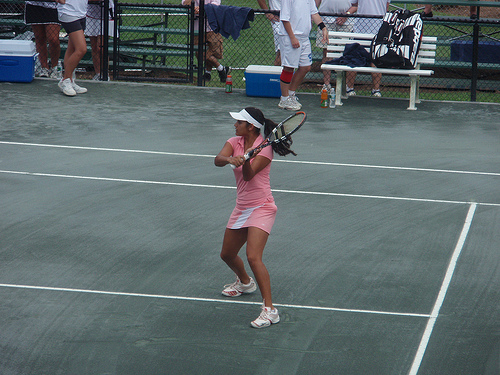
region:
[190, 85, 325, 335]
A woman playing tennis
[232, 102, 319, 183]
Tennis racket in the woman's hands.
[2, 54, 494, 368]
Tennis court is green.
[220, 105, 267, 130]
White visor on the woman's head.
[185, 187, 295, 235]
The woman is wearing a pink skirt.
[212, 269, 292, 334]
White sneakers on the woman.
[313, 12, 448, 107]
White bench against the fence.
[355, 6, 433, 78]
Black bag on the bench.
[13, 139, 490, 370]
White markings on the court.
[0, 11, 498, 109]
Fence surrounding the tennis court.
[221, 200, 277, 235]
white line in pink skirt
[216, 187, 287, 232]
small pink tennis skirt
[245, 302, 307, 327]
pink and white sneaker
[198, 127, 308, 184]
short sleeve pink shirt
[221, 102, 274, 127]
white sun visor on woman's head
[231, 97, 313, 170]
racket in player's hand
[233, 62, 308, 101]
blue and white cooler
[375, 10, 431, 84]
black and white equipment bag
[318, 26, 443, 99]
white bench on side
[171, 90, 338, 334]
woman playing tennis on court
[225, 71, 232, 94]
bottle of red gatorade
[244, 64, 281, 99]
blue and white cooler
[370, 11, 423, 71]
black and white bag on bench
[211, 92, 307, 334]
woman wearing pink shirt holding tennis racket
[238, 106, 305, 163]
black, white, and red tennis racket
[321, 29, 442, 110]
white bench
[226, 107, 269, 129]
white hat on woman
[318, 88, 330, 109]
orange bottle of gatorade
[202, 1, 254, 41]
black towel on fence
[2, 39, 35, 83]
blue and white cooler on the left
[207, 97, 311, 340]
A female tennis player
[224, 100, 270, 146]
A white visor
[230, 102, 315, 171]
A black and red tennis racket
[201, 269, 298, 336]
White tennis shoes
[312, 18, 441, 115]
A small white bench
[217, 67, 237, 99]
A bottle filled with red liquid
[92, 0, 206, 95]
Part of a gate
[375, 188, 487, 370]
A white line on the tennis court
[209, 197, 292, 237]
A pink tennis skirt with a white stripe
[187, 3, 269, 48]
A jacket hanging on the fence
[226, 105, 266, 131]
Visor worn by tennis player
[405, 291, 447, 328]
Lines painted on a tennis court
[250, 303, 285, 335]
Tennis shoes worn by tennis player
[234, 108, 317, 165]
Tennis racket held by tennis player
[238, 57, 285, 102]
Cooler on the tennis court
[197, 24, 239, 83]
Chain link fence surrounding a tennis court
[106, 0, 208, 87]
Entry gate in chain link fence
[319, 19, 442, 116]
Park bench on the tennis court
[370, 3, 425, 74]
Tennis bags on park bench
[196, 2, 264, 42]
Jacket folded over fence railing